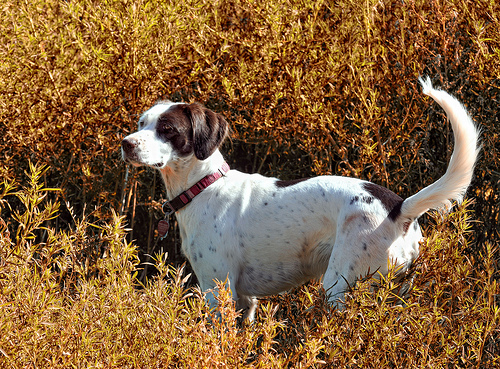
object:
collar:
[161, 161, 230, 213]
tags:
[155, 202, 174, 237]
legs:
[315, 247, 405, 314]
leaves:
[101, 285, 188, 338]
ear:
[190, 102, 231, 160]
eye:
[163, 124, 177, 135]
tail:
[402, 71, 487, 219]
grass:
[0, 0, 500, 369]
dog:
[120, 75, 484, 369]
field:
[0, 0, 500, 369]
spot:
[156, 103, 226, 161]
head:
[118, 100, 230, 169]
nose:
[118, 137, 139, 154]